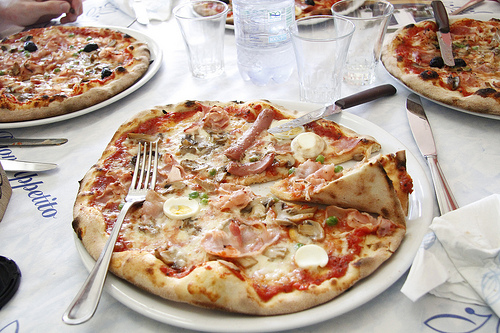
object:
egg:
[163, 196, 199, 220]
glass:
[291, 15, 355, 103]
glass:
[334, 0, 393, 87]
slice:
[270, 153, 410, 220]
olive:
[83, 44, 98, 52]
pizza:
[73, 100, 413, 316]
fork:
[62, 141, 158, 325]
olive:
[101, 68, 111, 78]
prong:
[149, 143, 158, 189]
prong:
[144, 142, 153, 189]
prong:
[129, 142, 141, 189]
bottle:
[231, 0, 298, 89]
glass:
[173, 0, 229, 79]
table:
[0, 0, 500, 330]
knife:
[267, 84, 396, 134]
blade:
[270, 104, 342, 133]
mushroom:
[295, 245, 328, 269]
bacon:
[203, 218, 278, 258]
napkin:
[401, 192, 499, 320]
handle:
[62, 201, 134, 325]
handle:
[334, 84, 396, 110]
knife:
[406, 95, 459, 216]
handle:
[426, 155, 458, 216]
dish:
[73, 99, 435, 332]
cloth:
[0, 0, 497, 331]